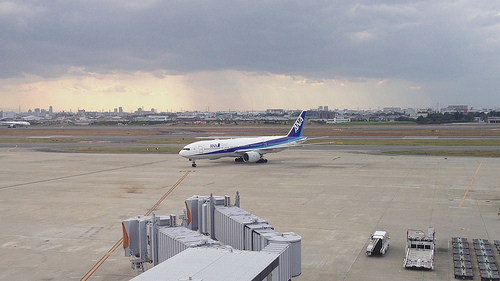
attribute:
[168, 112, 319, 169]
plane — Blue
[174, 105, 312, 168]
plane — white, commercial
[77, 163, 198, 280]
strip — orange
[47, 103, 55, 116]
buildings — tall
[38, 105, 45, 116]
buildings — tall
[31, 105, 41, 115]
buildings — tall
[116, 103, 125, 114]
buildings — tall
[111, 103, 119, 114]
buildings — tall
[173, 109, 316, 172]
plane — white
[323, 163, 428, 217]
concrete — grey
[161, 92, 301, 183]
airplane — white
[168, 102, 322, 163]
jet — white, blue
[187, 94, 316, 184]
plane — large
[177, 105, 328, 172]
jet — grounded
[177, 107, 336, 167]
airplane — commercial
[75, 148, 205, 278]
line — orange